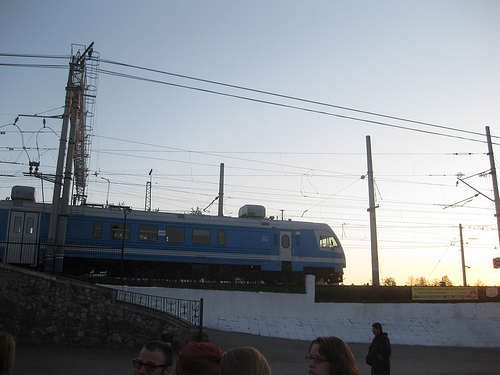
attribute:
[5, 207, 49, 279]
door — gray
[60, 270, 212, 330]
metal fencing — black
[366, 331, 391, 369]
clothing — black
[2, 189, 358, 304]
train — blue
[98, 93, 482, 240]
wires — electrical 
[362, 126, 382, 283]
electric pole — large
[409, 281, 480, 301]
sign — yellow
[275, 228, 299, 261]
door — white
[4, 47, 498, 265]
wires — electrical 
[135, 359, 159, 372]
sunglasses — black